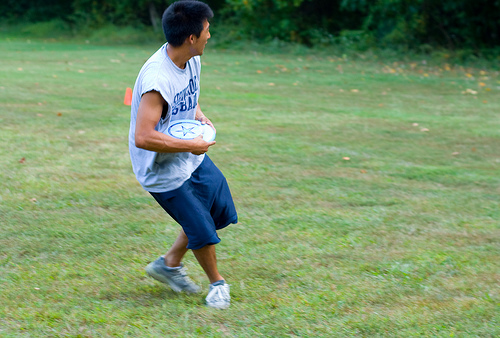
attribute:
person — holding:
[124, 1, 239, 313]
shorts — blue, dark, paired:
[141, 146, 241, 256]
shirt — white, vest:
[120, 42, 209, 198]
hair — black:
[154, 0, 215, 49]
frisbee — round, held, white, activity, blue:
[159, 118, 218, 154]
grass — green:
[276, 128, 493, 297]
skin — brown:
[132, 107, 164, 152]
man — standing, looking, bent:
[126, 0, 240, 313]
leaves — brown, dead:
[379, 58, 499, 103]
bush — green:
[310, 11, 446, 57]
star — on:
[173, 123, 198, 137]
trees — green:
[220, 0, 500, 60]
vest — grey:
[119, 39, 208, 197]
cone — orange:
[121, 86, 136, 111]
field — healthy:
[9, 41, 498, 336]